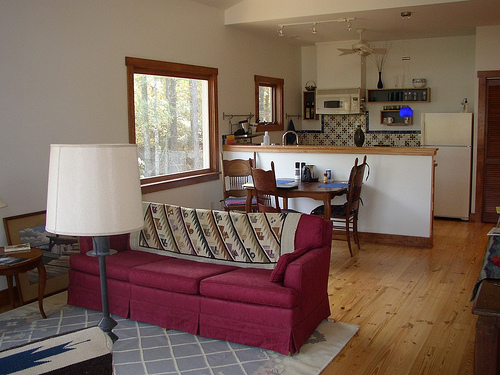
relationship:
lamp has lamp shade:
[32, 132, 154, 344] [44, 143, 148, 236]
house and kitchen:
[0, 0, 500, 375] [220, 10, 499, 251]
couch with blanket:
[66, 201, 334, 356] [90, 192, 307, 278]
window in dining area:
[125, 55, 224, 194] [222, 142, 382, 249]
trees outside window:
[137, 77, 200, 177] [122, 52, 224, 197]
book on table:
[0, 238, 33, 253] [1, 241, 63, 319]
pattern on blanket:
[147, 189, 297, 281] [136, 201, 289, 269]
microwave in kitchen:
[312, 85, 362, 115] [220, 10, 499, 251]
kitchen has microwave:
[220, 10, 499, 251] [312, 85, 362, 115]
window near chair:
[122, 52, 224, 197] [216, 150, 257, 212]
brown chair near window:
[218, 151, 258, 205] [122, 52, 224, 197]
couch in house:
[66, 201, 334, 356] [0, 0, 500, 375]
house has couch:
[0, 0, 500, 375] [66, 201, 334, 356]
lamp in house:
[43, 142, 145, 345] [0, 0, 500, 375]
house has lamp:
[0, 0, 500, 375] [43, 142, 145, 345]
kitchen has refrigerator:
[214, 0, 499, 250] [420, 112, 471, 220]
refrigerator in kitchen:
[420, 112, 471, 220] [214, 0, 499, 250]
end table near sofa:
[2, 242, 52, 323] [62, 198, 342, 361]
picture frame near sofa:
[2, 203, 97, 301] [62, 198, 342, 361]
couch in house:
[68, 196, 333, 354] [16, 16, 481, 353]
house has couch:
[16, 16, 481, 353] [68, 196, 333, 354]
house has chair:
[0, 0, 500, 375] [309, 155, 369, 255]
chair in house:
[309, 155, 369, 255] [0, 0, 500, 375]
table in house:
[243, 181, 343, 209] [16, 16, 481, 353]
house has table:
[16, 16, 481, 353] [243, 181, 343, 209]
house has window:
[0, 0, 500, 375] [122, 52, 224, 197]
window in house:
[122, 52, 224, 197] [0, 0, 500, 375]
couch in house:
[68, 196, 333, 354] [0, 0, 500, 375]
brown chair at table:
[218, 151, 258, 214] [238, 172, 352, 213]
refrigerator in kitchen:
[420, 112, 471, 220] [242, 58, 472, 241]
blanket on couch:
[131, 212, 303, 254] [66, 214, 331, 352]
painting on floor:
[3, 207, 86, 307] [1, 216, 491, 371]